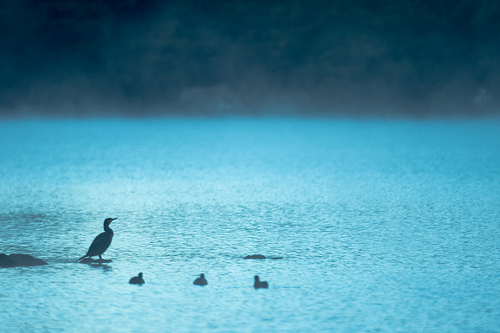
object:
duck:
[73, 217, 121, 264]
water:
[0, 119, 499, 333]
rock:
[0, 252, 48, 266]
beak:
[110, 214, 119, 224]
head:
[104, 214, 117, 223]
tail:
[73, 249, 96, 260]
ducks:
[78, 218, 116, 261]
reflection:
[56, 177, 276, 210]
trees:
[0, 0, 497, 97]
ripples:
[0, 156, 499, 333]